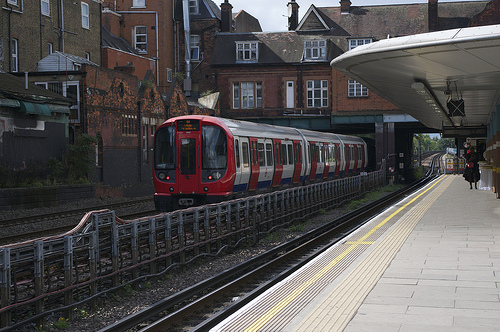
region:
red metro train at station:
[152, 105, 391, 187]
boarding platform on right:
[336, 112, 494, 279]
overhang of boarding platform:
[344, 40, 497, 103]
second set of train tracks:
[226, 190, 353, 298]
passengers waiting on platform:
[435, 119, 497, 219]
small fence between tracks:
[27, 192, 489, 289]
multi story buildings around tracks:
[20, 21, 492, 251]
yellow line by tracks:
[298, 198, 453, 279]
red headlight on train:
[200, 169, 212, 182]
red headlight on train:
[154, 167, 190, 185]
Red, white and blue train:
[155, 115, 368, 205]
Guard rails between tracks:
[0, 165, 392, 322]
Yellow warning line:
[243, 170, 450, 330]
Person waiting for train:
[461, 145, 481, 193]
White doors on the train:
[235, 137, 367, 183]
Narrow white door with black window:
[282, 78, 295, 109]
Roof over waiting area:
[323, 25, 496, 125]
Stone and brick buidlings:
[0, 0, 495, 190]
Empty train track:
[87, 147, 437, 328]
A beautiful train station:
[7, 5, 499, 328]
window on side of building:
[249, 49, 257, 61]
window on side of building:
[246, 51, 251, 59]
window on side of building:
[236, 50, 245, 62]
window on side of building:
[255, 97, 265, 108]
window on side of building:
[253, 83, 262, 95]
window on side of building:
[248, 94, 252, 104]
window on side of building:
[232, 95, 241, 107]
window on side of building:
[307, 48, 311, 55]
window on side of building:
[310, 47, 320, 58]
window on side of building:
[321, 80, 329, 91]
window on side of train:
[232, 140, 243, 168]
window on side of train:
[253, 143, 273, 163]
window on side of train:
[277, 145, 287, 164]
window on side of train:
[286, 143, 294, 165]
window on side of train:
[313, 149, 317, 164]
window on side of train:
[323, 147, 329, 160]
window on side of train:
[345, 145, 350, 158]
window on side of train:
[360, 145, 364, 158]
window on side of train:
[318, 145, 325, 165]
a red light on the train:
[201, 166, 216, 181]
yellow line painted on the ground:
[345, 230, 370, 248]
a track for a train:
[186, 284, 258, 309]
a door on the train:
[234, 134, 257, 181]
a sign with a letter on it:
[443, 85, 465, 124]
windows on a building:
[301, 68, 335, 111]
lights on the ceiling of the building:
[408, 70, 440, 115]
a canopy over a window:
[21, 94, 63, 118]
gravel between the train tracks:
[119, 263, 203, 293]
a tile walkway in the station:
[402, 249, 466, 316]